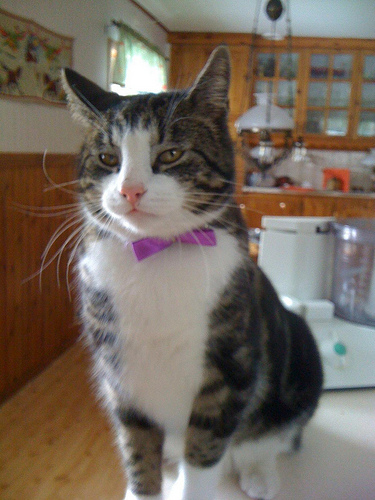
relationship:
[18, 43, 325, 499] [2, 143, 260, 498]
cat on table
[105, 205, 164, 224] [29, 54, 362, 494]
mouth of cat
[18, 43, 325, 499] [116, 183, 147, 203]
cat has nose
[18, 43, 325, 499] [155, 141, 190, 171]
cat has eye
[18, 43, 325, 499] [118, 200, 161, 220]
cat has mouth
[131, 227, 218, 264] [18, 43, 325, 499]
bow on cat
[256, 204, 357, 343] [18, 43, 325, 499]
processor behind cat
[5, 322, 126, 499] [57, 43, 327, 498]
table under cat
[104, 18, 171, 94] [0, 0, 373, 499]
curtains window in kitchen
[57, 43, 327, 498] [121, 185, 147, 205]
cat has nose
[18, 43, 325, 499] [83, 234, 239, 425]
cat has chest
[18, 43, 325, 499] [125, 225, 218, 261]
cat wearing ribbon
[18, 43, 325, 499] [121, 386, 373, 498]
cat on counter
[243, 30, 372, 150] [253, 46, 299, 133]
cabinets have glass door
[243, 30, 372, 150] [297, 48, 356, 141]
cabinets have glass door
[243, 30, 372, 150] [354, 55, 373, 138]
cabinets have glass door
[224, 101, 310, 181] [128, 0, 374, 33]
fixture hanging from ceiling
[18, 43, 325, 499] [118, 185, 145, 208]
cat has nose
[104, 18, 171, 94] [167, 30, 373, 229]
curtains window to left of cabinets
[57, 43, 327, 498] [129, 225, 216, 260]
cat wearing bow tie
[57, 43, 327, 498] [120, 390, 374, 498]
cat on table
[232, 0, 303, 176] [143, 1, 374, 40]
lamp hanging from ceiling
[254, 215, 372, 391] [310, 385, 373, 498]
blender on top of table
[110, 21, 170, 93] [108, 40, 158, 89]
curtain hanging on window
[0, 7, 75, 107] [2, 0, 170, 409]
picture hanging on wall